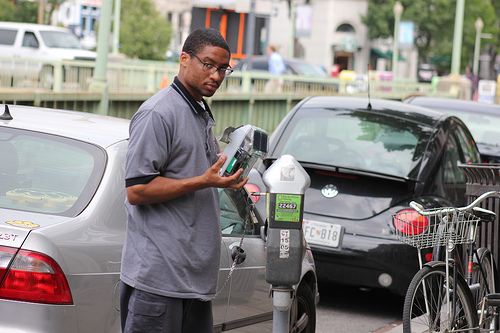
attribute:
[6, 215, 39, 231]
paw sticker — yellow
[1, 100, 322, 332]
car — gray, that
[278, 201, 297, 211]
numbers — white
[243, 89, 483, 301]
car — black, parked, that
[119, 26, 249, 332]
man — person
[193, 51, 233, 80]
glasses — black framed, black rimmed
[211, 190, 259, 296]
chain — silver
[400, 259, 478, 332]
tire — rubber, black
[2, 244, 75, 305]
taillight — red, white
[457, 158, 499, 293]
trashcan — metal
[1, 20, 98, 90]
van — white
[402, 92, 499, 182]
car — parked, that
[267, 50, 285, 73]
shirt — blue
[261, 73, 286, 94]
pants — khaki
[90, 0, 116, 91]
lamp post — light green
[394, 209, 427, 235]
brake light — red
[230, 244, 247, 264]
handle — black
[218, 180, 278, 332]
door — silver